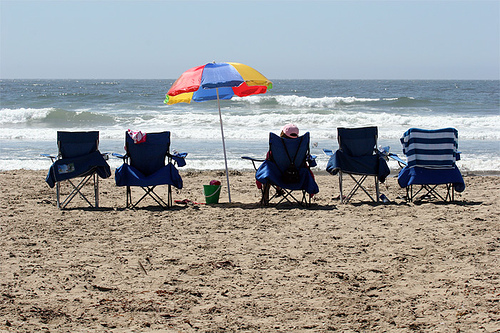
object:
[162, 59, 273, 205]
umbrella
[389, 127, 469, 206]
chairs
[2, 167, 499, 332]
beach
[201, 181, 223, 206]
sand pail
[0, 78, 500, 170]
body of water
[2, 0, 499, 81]
sky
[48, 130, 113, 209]
chair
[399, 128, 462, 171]
towel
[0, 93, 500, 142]
waves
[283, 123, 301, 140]
cap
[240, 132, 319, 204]
chair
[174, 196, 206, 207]
flip flops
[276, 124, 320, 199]
person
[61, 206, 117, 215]
shadow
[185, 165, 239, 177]
mound of sand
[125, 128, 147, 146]
cloth